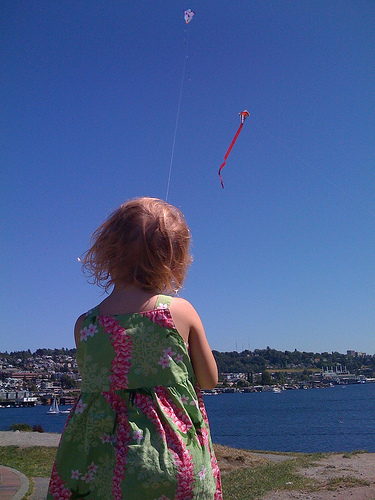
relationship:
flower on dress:
[156, 353, 177, 374] [42, 289, 228, 496]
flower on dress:
[161, 345, 178, 359] [42, 289, 228, 496]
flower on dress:
[172, 349, 186, 367] [42, 289, 228, 496]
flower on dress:
[176, 390, 192, 409] [42, 289, 228, 496]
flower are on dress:
[80, 323, 97, 339] [75, 310, 221, 498]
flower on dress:
[79, 323, 98, 342] [78, 311, 232, 491]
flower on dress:
[79, 323, 98, 342] [75, 310, 221, 498]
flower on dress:
[81, 460, 100, 484] [78, 311, 232, 491]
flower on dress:
[99, 432, 113, 444] [61, 309, 222, 493]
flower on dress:
[99, 432, 109, 444] [75, 310, 221, 498]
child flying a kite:
[71, 197, 219, 482] [178, 4, 200, 24]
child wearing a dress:
[45, 197, 221, 499] [75, 310, 221, 498]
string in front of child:
[174, 113, 178, 138] [71, 197, 219, 482]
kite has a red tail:
[232, 109, 257, 129] [224, 139, 236, 161]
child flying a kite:
[45, 197, 221, 499] [181, 6, 195, 23]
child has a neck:
[45, 197, 221, 499] [120, 280, 136, 291]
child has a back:
[45, 197, 221, 499] [126, 349, 168, 376]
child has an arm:
[45, 197, 221, 499] [193, 323, 210, 372]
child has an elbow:
[45, 197, 221, 499] [203, 379, 217, 389]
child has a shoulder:
[45, 197, 221, 499] [162, 295, 189, 310]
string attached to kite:
[172, 113, 185, 138] [178, 7, 197, 26]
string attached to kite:
[174, 113, 178, 138] [180, 8, 197, 22]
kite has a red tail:
[238, 109, 250, 123] [223, 144, 235, 158]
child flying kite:
[45, 197, 221, 499] [178, 4, 197, 25]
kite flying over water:
[238, 109, 250, 123] [4, 385, 372, 452]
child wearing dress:
[45, 197, 221, 499] [42, 289, 228, 496]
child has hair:
[45, 197, 221, 499] [79, 194, 199, 294]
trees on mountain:
[212, 349, 356, 372] [213, 342, 372, 379]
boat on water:
[45, 399, 73, 415] [4, 385, 372, 452]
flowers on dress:
[100, 308, 130, 486] [47, 291, 216, 493]